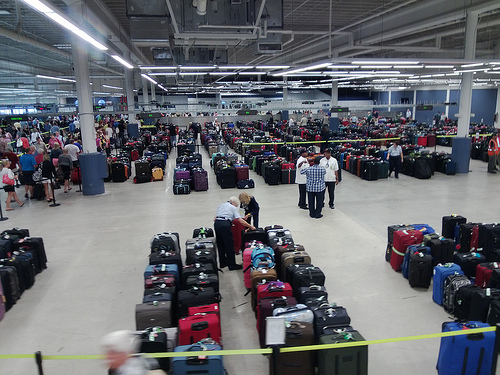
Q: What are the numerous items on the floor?
A: Luggage.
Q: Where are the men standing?
A: Middle of aisle.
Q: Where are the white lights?
A: Over head.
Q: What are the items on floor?
A: Suitcases.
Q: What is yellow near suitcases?
A: Rope.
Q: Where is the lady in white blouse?
A: Straight ahead.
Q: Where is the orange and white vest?
A: To the left side of picture.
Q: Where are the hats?
A: On the men's heads.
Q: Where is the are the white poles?
A: On left and the right side of the men.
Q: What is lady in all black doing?
A: Bending down.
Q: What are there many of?
A: Bags.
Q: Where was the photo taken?
A: At an airport.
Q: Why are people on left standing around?
A: Waiting on line.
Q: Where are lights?
A: On the ceiling.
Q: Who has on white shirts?
A: Two men.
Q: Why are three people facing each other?
A: People are talking.